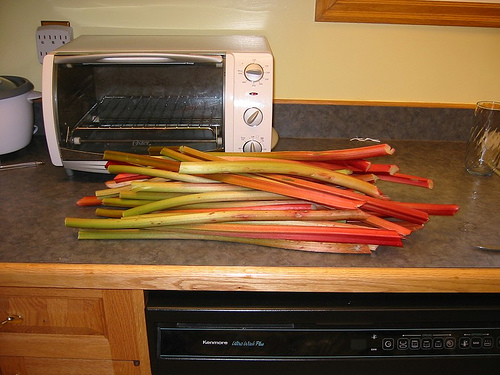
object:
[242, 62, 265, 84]
knob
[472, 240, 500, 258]
spoon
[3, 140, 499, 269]
counter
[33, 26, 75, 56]
outlet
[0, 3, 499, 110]
wall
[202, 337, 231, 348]
kenmore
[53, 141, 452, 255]
vegetable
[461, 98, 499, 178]
glass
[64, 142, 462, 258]
rhubarb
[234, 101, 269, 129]
knob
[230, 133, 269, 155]
knob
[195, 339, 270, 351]
words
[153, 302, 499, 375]
dishwasher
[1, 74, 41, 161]
pot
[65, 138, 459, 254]
stalk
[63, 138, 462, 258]
stick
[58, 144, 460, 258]
stick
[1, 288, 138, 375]
drawer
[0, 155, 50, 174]
pen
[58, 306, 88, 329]
brown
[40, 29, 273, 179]
cooker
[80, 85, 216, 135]
rack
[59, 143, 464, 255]
celery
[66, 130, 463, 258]
food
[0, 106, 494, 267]
table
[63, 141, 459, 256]
items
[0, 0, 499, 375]
kitchen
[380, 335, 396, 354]
buttons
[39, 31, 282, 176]
oven